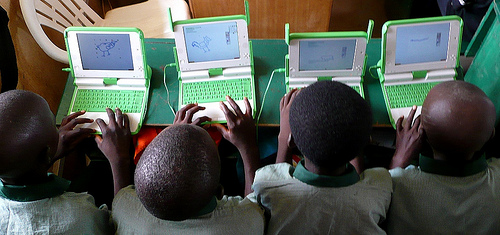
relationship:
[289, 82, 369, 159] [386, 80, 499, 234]
hair on boy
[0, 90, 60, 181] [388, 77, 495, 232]
head of one of students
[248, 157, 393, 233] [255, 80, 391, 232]
shirt of kid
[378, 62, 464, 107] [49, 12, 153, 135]
keyboard of laptop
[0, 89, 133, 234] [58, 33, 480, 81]
boy on laptops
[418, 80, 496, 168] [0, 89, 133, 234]
head of boy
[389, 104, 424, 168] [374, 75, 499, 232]
hand of child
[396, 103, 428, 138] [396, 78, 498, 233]
fingers of child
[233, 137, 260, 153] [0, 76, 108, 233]
wrist of child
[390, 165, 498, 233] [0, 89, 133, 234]
shirt of boy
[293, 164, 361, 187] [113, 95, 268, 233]
collar of boy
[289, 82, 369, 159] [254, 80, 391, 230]
hair of child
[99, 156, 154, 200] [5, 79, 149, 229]
arm of child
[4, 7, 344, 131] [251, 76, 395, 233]
bench with boy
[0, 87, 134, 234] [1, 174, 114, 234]
boy wearing shirt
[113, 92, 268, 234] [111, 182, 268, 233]
boy wearing shirt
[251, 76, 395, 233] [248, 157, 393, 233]
boy wearing shirt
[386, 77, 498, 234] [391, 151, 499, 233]
boy wearing shirt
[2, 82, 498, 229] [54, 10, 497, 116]
children using laptops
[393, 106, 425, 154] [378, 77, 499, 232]
hand of student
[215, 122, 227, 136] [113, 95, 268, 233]
finger of boy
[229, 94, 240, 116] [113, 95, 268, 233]
finger of boy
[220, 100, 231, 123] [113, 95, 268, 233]
finger of boy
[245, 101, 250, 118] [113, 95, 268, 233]
finger of boy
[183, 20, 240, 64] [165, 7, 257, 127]
screen on laptop